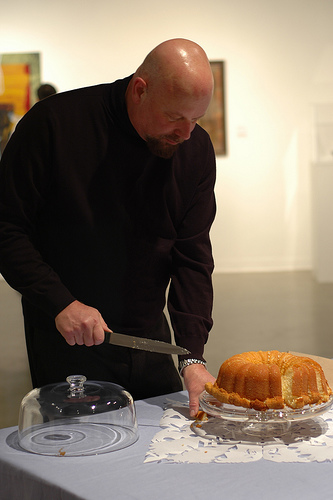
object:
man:
[0, 36, 218, 422]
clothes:
[1, 74, 217, 425]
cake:
[205, 350, 332, 411]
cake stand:
[200, 392, 333, 435]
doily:
[145, 396, 332, 462]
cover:
[18, 374, 139, 456]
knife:
[104, 331, 191, 356]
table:
[1, 381, 333, 500]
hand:
[54, 299, 112, 346]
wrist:
[178, 355, 205, 373]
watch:
[178, 359, 207, 376]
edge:
[200, 397, 333, 423]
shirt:
[0, 78, 217, 364]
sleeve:
[168, 123, 216, 364]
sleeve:
[1, 93, 75, 323]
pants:
[21, 295, 183, 422]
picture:
[196, 61, 224, 155]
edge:
[221, 62, 227, 156]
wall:
[1, 1, 333, 270]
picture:
[1, 54, 40, 157]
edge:
[37, 54, 42, 101]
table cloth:
[1, 389, 332, 499]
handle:
[104, 331, 110, 343]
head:
[125, 39, 213, 153]